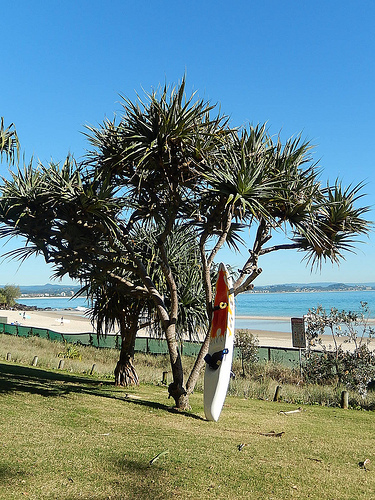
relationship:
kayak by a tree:
[199, 260, 228, 419] [4, 78, 329, 417]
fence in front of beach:
[0, 323, 342, 370] [1, 311, 374, 352]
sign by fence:
[288, 313, 308, 350] [1, 322, 373, 374]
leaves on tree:
[2, 66, 370, 331] [0, 71, 373, 408]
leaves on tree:
[3, 118, 23, 172] [2, 95, 200, 407]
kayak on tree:
[203, 261, 236, 423] [0, 71, 373, 408]